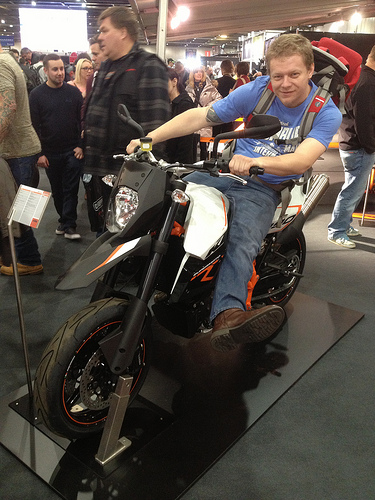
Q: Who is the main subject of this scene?
A: The man on the motorcycle.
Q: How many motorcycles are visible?
A: One.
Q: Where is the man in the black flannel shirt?
A: To the left of the motorcycle.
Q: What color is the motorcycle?
A: Black and orange.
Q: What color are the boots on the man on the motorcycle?
A: Brown.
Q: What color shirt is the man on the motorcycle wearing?
A: Blue and white.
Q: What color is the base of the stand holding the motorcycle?
A: Black.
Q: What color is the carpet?
A: Gray.